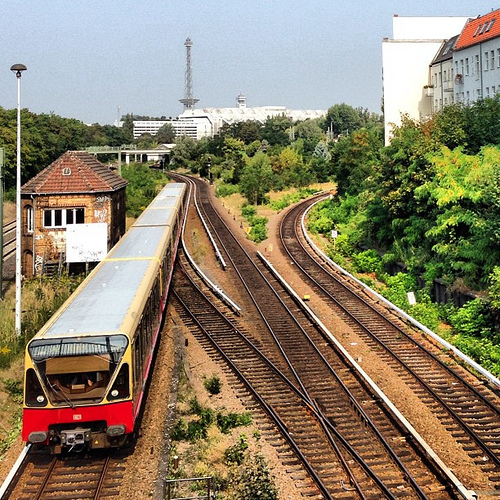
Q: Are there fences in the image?
A: No, there are no fences.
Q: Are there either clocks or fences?
A: No, there are no fences or clocks.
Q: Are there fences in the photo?
A: No, there are no fences.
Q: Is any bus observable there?
A: No, there are no buses.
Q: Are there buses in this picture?
A: No, there are no buses.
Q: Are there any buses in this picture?
A: No, there are no buses.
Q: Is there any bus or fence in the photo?
A: No, there are no buses or fences.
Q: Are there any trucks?
A: No, there are no trucks.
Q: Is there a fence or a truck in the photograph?
A: No, there are no trucks or fences.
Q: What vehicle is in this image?
A: The vehicle is a car.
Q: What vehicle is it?
A: The vehicle is a car.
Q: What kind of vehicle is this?
A: This is a car.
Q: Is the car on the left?
A: Yes, the car is on the left of the image.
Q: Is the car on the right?
A: No, the car is on the left of the image.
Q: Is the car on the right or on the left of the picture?
A: The car is on the left of the image.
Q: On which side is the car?
A: The car is on the left of the image.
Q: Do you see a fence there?
A: No, there are no fences.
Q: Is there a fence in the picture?
A: No, there are no fences.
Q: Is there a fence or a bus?
A: No, there are no fences or buses.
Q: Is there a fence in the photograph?
A: No, there are no fences.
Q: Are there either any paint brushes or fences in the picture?
A: No, there are no fences or paint brushes.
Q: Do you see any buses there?
A: No, there are no buses.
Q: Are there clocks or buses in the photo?
A: No, there are no buses or clocks.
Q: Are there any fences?
A: No, there are no fences.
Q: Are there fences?
A: No, there are no fences.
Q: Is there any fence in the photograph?
A: No, there are no fences.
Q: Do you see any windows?
A: Yes, there is a window.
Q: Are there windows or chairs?
A: Yes, there is a window.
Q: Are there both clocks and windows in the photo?
A: No, there is a window but no clocks.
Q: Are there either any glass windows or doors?
A: Yes, there is a glass window.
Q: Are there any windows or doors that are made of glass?
A: Yes, the window is made of glass.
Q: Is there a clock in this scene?
A: No, there are no clocks.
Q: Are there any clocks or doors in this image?
A: No, there are no clocks or doors.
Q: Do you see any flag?
A: No, there are no flags.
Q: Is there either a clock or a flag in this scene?
A: No, there are no flags or clocks.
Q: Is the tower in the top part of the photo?
A: Yes, the tower is in the top of the image.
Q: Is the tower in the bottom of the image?
A: No, the tower is in the top of the image.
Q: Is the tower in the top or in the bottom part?
A: The tower is in the top of the image.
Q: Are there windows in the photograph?
A: Yes, there is a window.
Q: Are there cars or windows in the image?
A: Yes, there is a window.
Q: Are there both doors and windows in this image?
A: No, there is a window but no doors.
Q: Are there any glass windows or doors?
A: Yes, there is a glass window.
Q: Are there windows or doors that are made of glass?
A: Yes, the window is made of glass.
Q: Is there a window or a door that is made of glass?
A: Yes, the window is made of glass.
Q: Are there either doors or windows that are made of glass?
A: Yes, the window is made of glass.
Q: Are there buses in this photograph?
A: No, there are no buses.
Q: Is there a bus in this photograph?
A: No, there are no buses.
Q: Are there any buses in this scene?
A: No, there are no buses.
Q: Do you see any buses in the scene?
A: No, there are no buses.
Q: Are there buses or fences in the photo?
A: No, there are no buses or fences.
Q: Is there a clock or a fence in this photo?
A: No, there are no fences or clocks.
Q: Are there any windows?
A: Yes, there is a window.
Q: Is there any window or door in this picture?
A: Yes, there is a window.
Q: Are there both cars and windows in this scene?
A: Yes, there are both a window and a car.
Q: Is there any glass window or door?
A: Yes, there is a glass window.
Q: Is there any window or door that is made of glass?
A: Yes, the window is made of glass.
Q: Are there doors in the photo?
A: No, there are no doors.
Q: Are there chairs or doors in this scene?
A: No, there are no doors or chairs.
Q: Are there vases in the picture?
A: No, there are no vases.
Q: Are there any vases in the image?
A: No, there are no vases.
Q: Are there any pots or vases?
A: No, there are no vases or pots.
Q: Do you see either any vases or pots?
A: No, there are no vases or pots.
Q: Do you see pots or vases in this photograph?
A: No, there are no vases or pots.